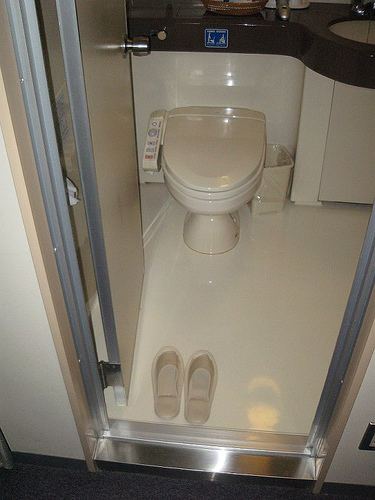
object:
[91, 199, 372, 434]
floor